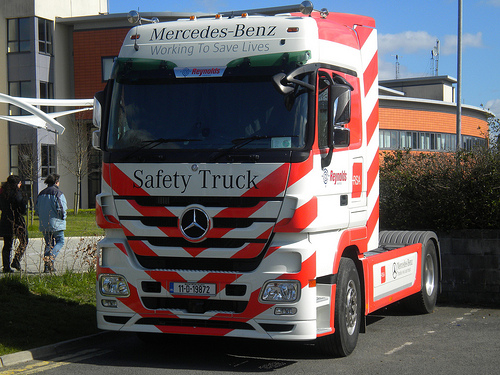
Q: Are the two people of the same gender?
A: Yes, all the people are female.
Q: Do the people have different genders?
A: No, all the people are female.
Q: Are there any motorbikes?
A: No, there are no motorbikes.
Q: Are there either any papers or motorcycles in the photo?
A: No, there are no motorcycles or papers.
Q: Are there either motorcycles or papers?
A: No, there are no motorcycles or papers.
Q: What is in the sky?
A: The clouds are in the sky.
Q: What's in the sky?
A: The clouds are in the sky.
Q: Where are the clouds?
A: The clouds are in the sky.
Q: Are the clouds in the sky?
A: Yes, the clouds are in the sky.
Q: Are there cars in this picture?
A: No, there are no cars.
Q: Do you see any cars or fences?
A: No, there are no cars or fences.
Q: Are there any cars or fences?
A: No, there are no cars or fences.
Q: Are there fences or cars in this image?
A: No, there are no cars or fences.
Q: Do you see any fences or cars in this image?
A: No, there are no cars or fences.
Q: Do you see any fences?
A: No, there are no fences.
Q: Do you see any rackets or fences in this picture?
A: No, there are no fences or rackets.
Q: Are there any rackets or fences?
A: No, there are no fences or rackets.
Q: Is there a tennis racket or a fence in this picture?
A: No, there are no fences or rackets.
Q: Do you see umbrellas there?
A: No, there are no umbrellas.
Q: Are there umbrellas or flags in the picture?
A: No, there are no umbrellas or flags.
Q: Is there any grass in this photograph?
A: Yes, there is grass.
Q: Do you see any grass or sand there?
A: Yes, there is grass.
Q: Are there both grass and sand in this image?
A: No, there is grass but no sand.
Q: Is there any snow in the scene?
A: No, there is no snow.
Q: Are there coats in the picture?
A: Yes, there is a coat.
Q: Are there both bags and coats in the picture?
A: No, there is a coat but no bags.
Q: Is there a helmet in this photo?
A: No, there are no helmets.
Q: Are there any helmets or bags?
A: No, there are no helmets or bags.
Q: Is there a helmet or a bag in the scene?
A: No, there are no helmets or bags.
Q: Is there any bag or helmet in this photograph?
A: No, there are no helmets or bags.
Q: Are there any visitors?
A: No, there are no visitors.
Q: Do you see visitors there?
A: No, there are no visitors.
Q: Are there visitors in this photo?
A: No, there are no visitors.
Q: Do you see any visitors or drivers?
A: No, there are no visitors or drivers.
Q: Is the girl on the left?
A: Yes, the girl is on the left of the image.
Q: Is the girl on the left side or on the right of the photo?
A: The girl is on the left of the image.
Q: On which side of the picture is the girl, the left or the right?
A: The girl is on the left of the image.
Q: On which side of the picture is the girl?
A: The girl is on the left of the image.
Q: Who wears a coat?
A: The girl wears a coat.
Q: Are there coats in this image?
A: Yes, there is a coat.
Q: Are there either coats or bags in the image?
A: Yes, there is a coat.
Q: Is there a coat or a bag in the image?
A: Yes, there is a coat.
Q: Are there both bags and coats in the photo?
A: No, there is a coat but no bags.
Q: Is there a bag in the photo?
A: No, there are no bags.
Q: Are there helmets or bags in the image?
A: No, there are no bags or helmets.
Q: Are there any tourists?
A: No, there are no tourists.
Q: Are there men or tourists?
A: No, there are no tourists or men.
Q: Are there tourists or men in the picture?
A: No, there are no tourists or men.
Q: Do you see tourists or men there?
A: No, there are no tourists or men.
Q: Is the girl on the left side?
A: Yes, the girl is on the left of the image.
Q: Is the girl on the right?
A: No, the girl is on the left of the image.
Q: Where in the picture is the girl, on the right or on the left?
A: The girl is on the left of the image.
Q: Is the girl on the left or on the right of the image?
A: The girl is on the left of the image.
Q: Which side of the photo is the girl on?
A: The girl is on the left of the image.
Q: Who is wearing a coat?
A: The girl is wearing a coat.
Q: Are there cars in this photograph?
A: No, there are no cars.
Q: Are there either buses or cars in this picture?
A: No, there are no cars or buses.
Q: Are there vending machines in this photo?
A: No, there are no vending machines.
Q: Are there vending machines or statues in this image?
A: No, there are no vending machines or statues.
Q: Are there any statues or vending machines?
A: No, there are no vending machines or statues.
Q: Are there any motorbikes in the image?
A: No, there are no motorbikes.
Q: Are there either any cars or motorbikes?
A: No, there are no motorbikes or cars.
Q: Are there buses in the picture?
A: No, there are no buses.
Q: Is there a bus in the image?
A: No, there are no buses.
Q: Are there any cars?
A: No, there are no cars.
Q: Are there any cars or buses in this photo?
A: No, there are no cars or buses.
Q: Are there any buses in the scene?
A: No, there are no buses.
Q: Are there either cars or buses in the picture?
A: No, there are no buses or cars.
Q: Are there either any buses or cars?
A: No, there are no buses or cars.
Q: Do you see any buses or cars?
A: No, there are no buses or cars.